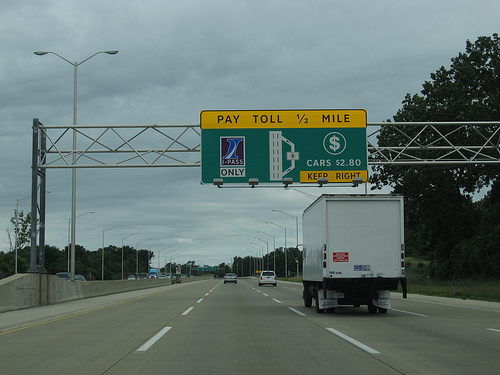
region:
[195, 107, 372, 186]
a green and yellow highway sign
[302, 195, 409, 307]
part of a white truck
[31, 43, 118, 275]
a tall gray street lamp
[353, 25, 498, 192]
part of a large green tree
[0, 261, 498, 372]
part of a highway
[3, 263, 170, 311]
a long concrete road barrier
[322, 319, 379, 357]
a long white line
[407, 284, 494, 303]
a section of green grass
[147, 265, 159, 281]
part of a blue truck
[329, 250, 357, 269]
warning sticker on the truck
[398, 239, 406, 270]
three lights on the rear of the truck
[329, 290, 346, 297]
license plate on the truck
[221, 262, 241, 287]
Car driving ahead in the distance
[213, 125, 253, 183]
sign for the EZ Pass toll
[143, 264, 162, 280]
Blue truck in the approaching lane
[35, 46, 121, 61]
Lights on top on of the pole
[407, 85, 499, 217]
Big trees with leaves on it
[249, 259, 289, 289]
White car in the right lane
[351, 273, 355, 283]
part of a wheel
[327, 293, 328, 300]
edge of a wheel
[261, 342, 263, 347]
side of a road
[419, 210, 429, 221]
part of a bush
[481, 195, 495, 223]
part of a pavement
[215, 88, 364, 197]
large green sign on pole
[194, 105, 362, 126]
yellow bar on top of sign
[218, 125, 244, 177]
image on side of sign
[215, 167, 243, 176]
black writing on sign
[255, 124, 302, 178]
white image on sign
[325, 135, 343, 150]
white dollar sign on sign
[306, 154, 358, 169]
white writing on sign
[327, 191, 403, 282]
back of large white truck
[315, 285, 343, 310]
white mud flaps on truck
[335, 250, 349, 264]
red sign on back of truck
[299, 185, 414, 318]
Truck on the road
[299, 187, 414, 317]
Truck is on the road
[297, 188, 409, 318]
Truck on the freeway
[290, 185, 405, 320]
Truck is on the freeway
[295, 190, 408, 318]
Truck on the street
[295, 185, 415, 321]
Truck is on the street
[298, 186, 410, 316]
White truck on the road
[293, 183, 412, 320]
White truck on the freeway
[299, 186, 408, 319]
White truck is on the freeway